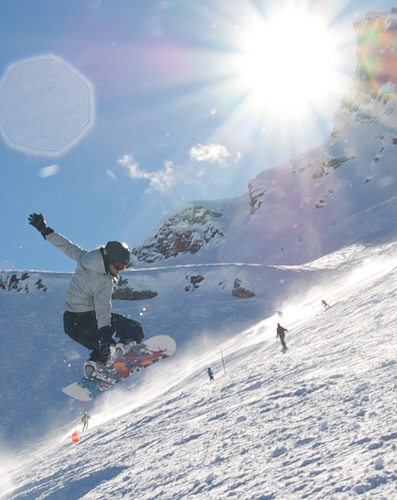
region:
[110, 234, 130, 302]
This person is wearing a helmet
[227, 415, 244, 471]
There is bright white snow here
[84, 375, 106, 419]
There is a decorated bottom of a surfboard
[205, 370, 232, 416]
This person is wearing a blue coat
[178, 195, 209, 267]
There are majestic mountains in the distance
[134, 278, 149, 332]
There are many rock faces right here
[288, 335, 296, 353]
This person is holding a ski pole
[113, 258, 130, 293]
This person is wearing a pair of goggles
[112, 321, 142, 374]
This person is wearing black snow pants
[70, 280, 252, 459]
Jackson Mingus took this photo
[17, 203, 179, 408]
this person is snowboarding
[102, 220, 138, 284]
the person is wearing a helmet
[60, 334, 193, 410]
the board is white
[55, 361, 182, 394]
the board has multi color designs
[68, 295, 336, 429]
5 skiers or boarders are in the back ground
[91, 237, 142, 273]
this person is wearing goggles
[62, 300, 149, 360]
he wears black pants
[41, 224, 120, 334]
the jacket is white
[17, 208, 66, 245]
he has on black gloves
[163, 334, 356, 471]
the snow appears to be well traversed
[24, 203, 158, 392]
snowboarder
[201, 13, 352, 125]
yellow sun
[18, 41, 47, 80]
white clouds in blue sky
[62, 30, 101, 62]
white clouds in blue sky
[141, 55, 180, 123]
white clouds in blue sky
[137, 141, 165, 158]
white clouds in blue sky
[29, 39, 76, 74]
white clouds in blue sky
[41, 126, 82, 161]
white clouds in blue sky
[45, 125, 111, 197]
white clouds in blue sky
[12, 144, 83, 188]
white clouds in blue sky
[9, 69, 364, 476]
this is a ski slope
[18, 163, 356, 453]
this is a mountain side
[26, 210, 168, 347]
this is a snowboarder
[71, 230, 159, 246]
the snowboarder has a helmet on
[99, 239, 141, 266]
the helmet is black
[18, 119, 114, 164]
these are light glares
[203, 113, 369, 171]
this is the sun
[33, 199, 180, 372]
the snowboarder has a white jacket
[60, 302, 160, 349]
the snowboarder has black pants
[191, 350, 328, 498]
the snow is very bright white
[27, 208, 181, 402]
snow boarder on a snowy hill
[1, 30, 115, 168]
lens flare in the sky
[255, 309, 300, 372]
person on skis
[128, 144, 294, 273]
mountain with low flying clouds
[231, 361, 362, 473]
roughed up snow on a hill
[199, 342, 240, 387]
person walking by marking in snow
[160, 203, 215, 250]
rocky mountain with snow on it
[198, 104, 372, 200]
sun rays in the blue sky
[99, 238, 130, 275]
helmet and face googles on the snowboarder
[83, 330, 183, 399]
colorful snowboard midair